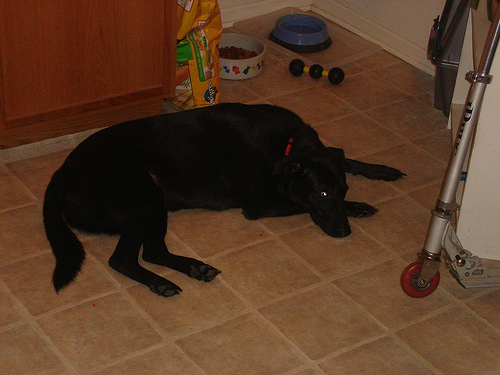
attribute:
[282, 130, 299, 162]
collar — red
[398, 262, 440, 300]
wheel — red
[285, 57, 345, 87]
toy — black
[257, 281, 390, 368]
tile — brown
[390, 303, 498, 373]
tile — brown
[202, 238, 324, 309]
tile — brown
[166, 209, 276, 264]
tile — brown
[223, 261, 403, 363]
floor — tan,  square, tiled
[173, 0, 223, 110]
bag — yellow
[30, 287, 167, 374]
tile — brown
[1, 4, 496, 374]
floor — tiled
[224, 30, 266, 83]
dog dish — large, white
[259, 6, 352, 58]
bowl — blue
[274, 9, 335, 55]
bowl — blue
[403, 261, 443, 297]
wheel — red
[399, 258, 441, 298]
wheel — red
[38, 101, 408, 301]
dog — black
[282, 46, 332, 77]
toy — small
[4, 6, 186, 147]
cabinet — wooden